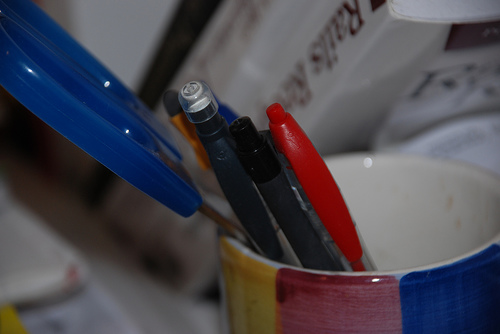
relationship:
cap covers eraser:
[177, 80, 219, 124] [181, 81, 203, 103]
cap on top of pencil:
[177, 80, 219, 124] [178, 80, 297, 267]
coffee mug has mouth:
[216, 150, 500, 334] [231, 156, 499, 273]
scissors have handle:
[1, 0, 268, 259] [1, 1, 203, 218]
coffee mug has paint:
[216, 150, 500, 334] [275, 267, 402, 334]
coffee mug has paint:
[216, 150, 500, 334] [399, 243, 499, 333]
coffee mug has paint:
[216, 150, 500, 334] [217, 232, 278, 334]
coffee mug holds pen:
[216, 150, 500, 334] [265, 101, 376, 272]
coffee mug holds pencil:
[216, 150, 500, 334] [178, 80, 297, 267]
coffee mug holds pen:
[216, 150, 500, 334] [226, 115, 351, 273]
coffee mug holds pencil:
[216, 150, 500, 334] [161, 89, 215, 173]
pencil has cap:
[178, 80, 297, 267] [177, 80, 219, 124]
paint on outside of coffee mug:
[399, 243, 499, 333] [216, 150, 500, 334]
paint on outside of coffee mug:
[275, 267, 402, 334] [216, 150, 500, 334]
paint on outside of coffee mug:
[217, 232, 278, 334] [216, 150, 500, 334]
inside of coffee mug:
[231, 156, 499, 273] [216, 150, 500, 334]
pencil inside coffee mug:
[161, 89, 215, 173] [216, 150, 500, 334]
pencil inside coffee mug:
[178, 80, 297, 267] [216, 150, 500, 334]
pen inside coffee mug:
[265, 101, 376, 272] [216, 150, 500, 334]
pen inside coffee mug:
[226, 115, 351, 273] [216, 150, 500, 334]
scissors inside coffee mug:
[1, 0, 268, 259] [216, 150, 500, 334]